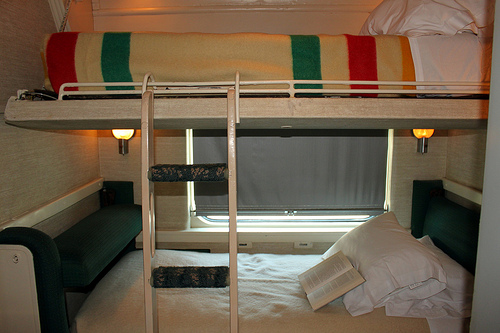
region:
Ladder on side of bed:
[130, 63, 274, 332]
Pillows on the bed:
[285, 188, 488, 324]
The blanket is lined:
[250, 3, 463, 100]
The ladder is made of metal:
[117, 110, 291, 330]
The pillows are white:
[343, 187, 473, 326]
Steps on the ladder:
[145, 123, 240, 290]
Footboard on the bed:
[31, 176, 136, 324]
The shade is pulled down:
[250, 143, 486, 263]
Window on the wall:
[180, 88, 413, 246]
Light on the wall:
[397, 120, 447, 159]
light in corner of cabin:
[398, 130, 444, 155]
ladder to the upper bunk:
[123, 91, 240, 331]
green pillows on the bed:
[71, 202, 146, 295]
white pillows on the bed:
[353, 235, 464, 328]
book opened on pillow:
[295, 237, 355, 310]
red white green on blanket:
[52, 36, 402, 90]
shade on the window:
[235, 133, 387, 220]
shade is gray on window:
[236, 137, 386, 226]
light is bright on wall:
[108, 125, 134, 168]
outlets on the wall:
[232, 237, 324, 254]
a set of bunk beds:
[5, 9, 491, 331]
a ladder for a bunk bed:
[128, 69, 250, 332]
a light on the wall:
[110, 126, 137, 151]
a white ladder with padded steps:
[134, 89, 244, 326]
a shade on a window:
[185, 129, 397, 220]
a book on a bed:
[295, 248, 372, 316]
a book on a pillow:
[293, 244, 367, 314]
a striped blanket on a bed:
[35, 23, 432, 100]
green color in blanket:
[294, 43, 316, 73]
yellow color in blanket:
[328, 44, 340, 71]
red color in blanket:
[356, 44, 366, 76]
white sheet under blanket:
[434, 51, 454, 71]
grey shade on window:
[276, 147, 305, 168]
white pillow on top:
[374, 246, 393, 269]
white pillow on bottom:
[453, 271, 460, 293]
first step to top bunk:
[151, 265, 226, 295]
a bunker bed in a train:
[0, 2, 492, 331]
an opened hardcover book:
[297, 249, 364, 311]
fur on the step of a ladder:
[150, 263, 230, 288]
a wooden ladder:
[141, 90, 238, 331]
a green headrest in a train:
[53, 200, 143, 292]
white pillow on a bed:
[323, 210, 474, 320]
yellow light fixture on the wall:
[413, 128, 433, 153]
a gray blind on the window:
[191, 131, 388, 214]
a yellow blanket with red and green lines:
[43, 30, 403, 95]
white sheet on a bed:
[408, 32, 489, 98]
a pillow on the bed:
[327, 208, 460, 328]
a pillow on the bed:
[388, 220, 448, 327]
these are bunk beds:
[62, 51, 387, 296]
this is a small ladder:
[163, 129, 245, 331]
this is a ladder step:
[135, 139, 292, 215]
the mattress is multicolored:
[87, 34, 472, 161]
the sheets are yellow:
[103, 5, 346, 95]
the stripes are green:
[231, 4, 357, 132]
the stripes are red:
[329, 24, 393, 113]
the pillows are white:
[231, 229, 455, 323]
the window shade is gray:
[228, 140, 374, 188]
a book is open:
[298, 248, 380, 327]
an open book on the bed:
[271, 232, 375, 313]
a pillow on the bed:
[328, 215, 427, 331]